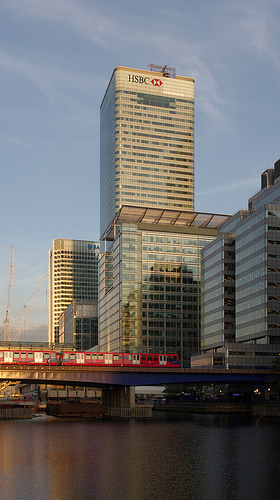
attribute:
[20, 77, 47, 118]
clouds — white 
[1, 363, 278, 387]
bridge — blue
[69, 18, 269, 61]
clouds — white 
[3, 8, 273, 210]
sky — blue 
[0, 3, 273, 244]
sky — blue 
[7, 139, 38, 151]
clouds — white 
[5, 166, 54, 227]
sky — blue 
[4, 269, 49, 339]
crane — white, orange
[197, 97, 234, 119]
cloud — white 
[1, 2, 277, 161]
sky — blue 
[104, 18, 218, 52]
clouds — white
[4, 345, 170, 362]
train — red 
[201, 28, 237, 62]
clouds — white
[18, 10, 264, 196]
sky — blue 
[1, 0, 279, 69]
sky — blue 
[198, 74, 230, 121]
cloud — white 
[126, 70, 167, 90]
sign — black , white 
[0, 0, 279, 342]
clouds — white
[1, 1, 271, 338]
sky — blue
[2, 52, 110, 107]
cloud — white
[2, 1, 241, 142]
cloud — white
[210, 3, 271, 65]
cloud — white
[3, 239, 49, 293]
cloud — white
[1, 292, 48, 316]
cloud — white